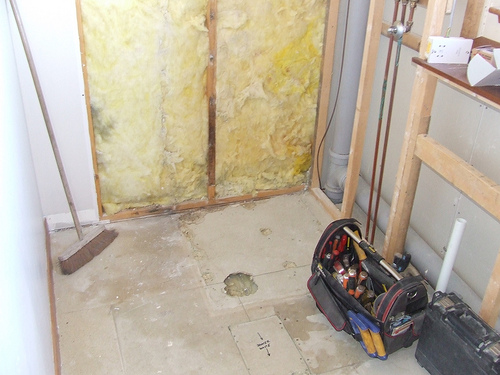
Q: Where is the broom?
A: Left back corner.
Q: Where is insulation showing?
A: Back wall.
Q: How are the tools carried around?
A: In the tool bag.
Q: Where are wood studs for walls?
A: Right side.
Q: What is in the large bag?
A: Tools.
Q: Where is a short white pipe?
A: Behind tool bag.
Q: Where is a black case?
A: Far right.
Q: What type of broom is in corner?
A: A push broom.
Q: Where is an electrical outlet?
A: On shelf above bags.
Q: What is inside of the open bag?
A: Lots of tools.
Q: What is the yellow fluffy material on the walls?
A: Insulation.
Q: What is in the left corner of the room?
A: A broom.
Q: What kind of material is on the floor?
A: Concrete.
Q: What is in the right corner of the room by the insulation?
A: A pipe.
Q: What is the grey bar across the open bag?
A: A handlebar.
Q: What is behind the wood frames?
A: Plumbing.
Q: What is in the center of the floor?
A: A hole in the concrete.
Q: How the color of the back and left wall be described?
A: Light blue.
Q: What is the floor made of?
A: Tiles.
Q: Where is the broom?
A: On the left.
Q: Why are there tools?
A: For repair.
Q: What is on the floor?
A: Tool box.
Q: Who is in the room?
A: No one.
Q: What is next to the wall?
A: Broom.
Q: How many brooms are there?
A: 1.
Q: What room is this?
A: Bathroom.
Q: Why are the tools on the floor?
A: They are not being used.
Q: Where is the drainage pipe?
A: Next to the wall.